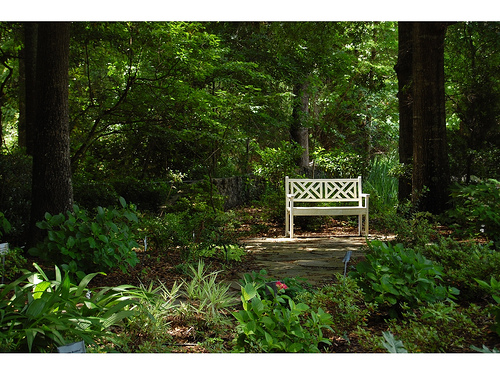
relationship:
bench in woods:
[284, 175, 370, 239] [2, 23, 495, 351]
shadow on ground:
[255, 240, 352, 282] [260, 255, 315, 282]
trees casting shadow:
[230, 21, 385, 154] [255, 240, 352, 282]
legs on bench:
[284, 207, 371, 235] [277, 173, 376, 239]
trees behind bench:
[2, 21, 483, 227] [269, 154, 401, 241]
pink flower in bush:
[273, 280, 291, 293] [232, 268, 335, 354]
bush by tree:
[36, 185, 183, 270] [25, 19, 75, 250]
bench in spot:
[284, 175, 370, 239] [236, 229, 396, 255]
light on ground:
[241, 230, 397, 253] [11, 207, 496, 339]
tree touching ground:
[403, 23, 448, 216] [382, 130, 419, 185]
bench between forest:
[284, 175, 370, 239] [8, 70, 489, 195]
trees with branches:
[2, 21, 500, 228] [68, 98, 118, 159]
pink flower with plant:
[275, 281, 288, 290] [230, 265, 340, 345]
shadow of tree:
[288, 248, 353, 283] [61, 65, 183, 199]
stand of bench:
[265, 211, 376, 230] [272, 163, 383, 238]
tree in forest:
[75, 70, 281, 204] [7, 120, 494, 246]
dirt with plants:
[217, 213, 440, 371] [231, 237, 461, 353]